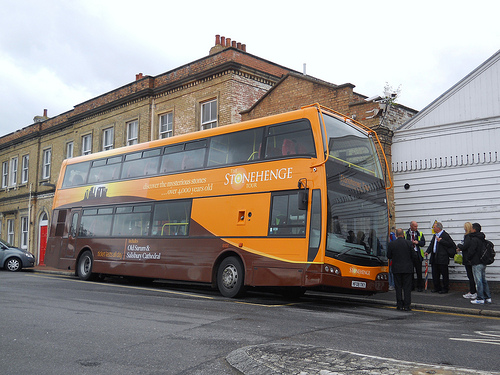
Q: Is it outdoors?
A: Yes, it is outdoors.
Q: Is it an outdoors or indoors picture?
A: It is outdoors.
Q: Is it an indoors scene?
A: No, it is outdoors.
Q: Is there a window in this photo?
A: Yes, there are windows.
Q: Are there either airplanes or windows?
A: Yes, there are windows.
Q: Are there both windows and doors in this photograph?
A: Yes, there are both windows and a door.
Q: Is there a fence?
A: No, there are no fences.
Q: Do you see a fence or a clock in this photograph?
A: No, there are no fences or clocks.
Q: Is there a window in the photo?
A: Yes, there are windows.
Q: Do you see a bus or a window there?
A: Yes, there are windows.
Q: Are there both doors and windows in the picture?
A: Yes, there are both windows and a door.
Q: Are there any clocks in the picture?
A: No, there are no clocks.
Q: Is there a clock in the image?
A: No, there are no clocks.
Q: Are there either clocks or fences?
A: No, there are no clocks or fences.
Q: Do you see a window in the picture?
A: Yes, there are windows.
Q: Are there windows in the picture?
A: Yes, there are windows.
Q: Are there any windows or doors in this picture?
A: Yes, there are windows.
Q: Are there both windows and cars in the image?
A: Yes, there are both windows and a car.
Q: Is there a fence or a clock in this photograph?
A: No, there are no fences or clocks.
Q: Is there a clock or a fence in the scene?
A: No, there are no fences or clocks.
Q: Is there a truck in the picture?
A: No, there are no trucks.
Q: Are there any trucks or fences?
A: No, there are no trucks or fences.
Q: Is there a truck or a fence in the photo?
A: No, there are no trucks or fences.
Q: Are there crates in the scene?
A: No, there are no crates.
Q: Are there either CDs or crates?
A: No, there are no crates or cds.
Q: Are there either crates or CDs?
A: No, there are no crates or cds.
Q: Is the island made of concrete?
A: Yes, the island is made of concrete.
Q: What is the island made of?
A: The island is made of concrete.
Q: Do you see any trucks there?
A: No, there are no trucks.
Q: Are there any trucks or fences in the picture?
A: No, there are no trucks or fences.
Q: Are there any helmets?
A: No, there are no helmets.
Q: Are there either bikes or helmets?
A: No, there are no helmets or bikes.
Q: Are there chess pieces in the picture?
A: No, there are no chess pieces.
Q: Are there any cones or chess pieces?
A: No, there are no chess pieces or cones.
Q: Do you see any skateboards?
A: No, there are no skateboards.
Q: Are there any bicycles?
A: No, there are no bicycles.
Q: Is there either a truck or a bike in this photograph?
A: No, there are no bikes or trucks.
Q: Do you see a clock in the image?
A: No, there are no clocks.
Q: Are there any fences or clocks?
A: No, there are no clocks or fences.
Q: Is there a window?
A: Yes, there is a window.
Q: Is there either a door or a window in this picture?
A: Yes, there is a window.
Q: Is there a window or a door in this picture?
A: Yes, there is a window.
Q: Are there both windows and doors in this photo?
A: Yes, there are both a window and a door.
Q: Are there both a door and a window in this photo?
A: Yes, there are both a window and a door.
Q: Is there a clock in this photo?
A: No, there are no clocks.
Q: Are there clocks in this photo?
A: No, there are no clocks.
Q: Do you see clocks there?
A: No, there are no clocks.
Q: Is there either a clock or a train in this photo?
A: No, there are no clocks or trains.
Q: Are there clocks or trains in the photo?
A: No, there are no clocks or trains.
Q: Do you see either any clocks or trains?
A: No, there are no clocks or trains.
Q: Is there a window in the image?
A: Yes, there are windows.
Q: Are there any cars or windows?
A: Yes, there are windows.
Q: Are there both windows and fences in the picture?
A: No, there are windows but no fences.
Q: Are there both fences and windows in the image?
A: No, there are windows but no fences.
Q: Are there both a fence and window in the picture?
A: No, there are windows but no fences.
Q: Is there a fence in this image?
A: No, there are no fences.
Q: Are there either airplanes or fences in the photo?
A: No, there are no fences or airplanes.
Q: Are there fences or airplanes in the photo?
A: No, there are no fences or airplanes.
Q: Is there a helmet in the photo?
A: No, there are no helmets.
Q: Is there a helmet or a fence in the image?
A: No, there are no helmets or fences.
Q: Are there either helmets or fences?
A: No, there are no helmets or fences.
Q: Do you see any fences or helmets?
A: No, there are no helmets or fences.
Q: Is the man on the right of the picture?
A: Yes, the man is on the right of the image.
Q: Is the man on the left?
A: No, the man is on the right of the image.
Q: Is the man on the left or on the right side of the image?
A: The man is on the right of the image.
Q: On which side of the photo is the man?
A: The man is on the right of the image.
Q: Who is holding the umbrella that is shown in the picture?
A: The man is holding the umbrella.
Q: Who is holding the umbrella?
A: The man is holding the umbrella.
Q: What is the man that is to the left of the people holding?
A: The man is holding the umbrella.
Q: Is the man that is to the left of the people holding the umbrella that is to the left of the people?
A: Yes, the man is holding the umbrella.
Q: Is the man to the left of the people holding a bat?
A: No, the man is holding the umbrella.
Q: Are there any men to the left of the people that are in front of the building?
A: Yes, there is a man to the left of the people.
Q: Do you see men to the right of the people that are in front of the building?
A: No, the man is to the left of the people.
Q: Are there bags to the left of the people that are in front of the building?
A: No, there is a man to the left of the people.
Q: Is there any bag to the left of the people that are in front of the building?
A: No, there is a man to the left of the people.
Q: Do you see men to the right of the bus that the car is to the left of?
A: Yes, there is a man to the right of the bus.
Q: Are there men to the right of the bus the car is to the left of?
A: Yes, there is a man to the right of the bus.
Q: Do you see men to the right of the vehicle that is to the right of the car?
A: Yes, there is a man to the right of the bus.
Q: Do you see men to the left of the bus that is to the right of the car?
A: No, the man is to the right of the bus.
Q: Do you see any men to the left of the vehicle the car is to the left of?
A: No, the man is to the right of the bus.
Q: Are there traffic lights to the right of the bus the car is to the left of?
A: No, there is a man to the right of the bus.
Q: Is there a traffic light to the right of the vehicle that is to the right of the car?
A: No, there is a man to the right of the bus.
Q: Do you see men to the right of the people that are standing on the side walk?
A: Yes, there is a man to the right of the people.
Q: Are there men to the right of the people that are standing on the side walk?
A: Yes, there is a man to the right of the people.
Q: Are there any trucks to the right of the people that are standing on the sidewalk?
A: No, there is a man to the right of the people.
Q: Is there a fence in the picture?
A: No, there are no fences.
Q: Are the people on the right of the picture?
A: Yes, the people are on the right of the image.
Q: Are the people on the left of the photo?
A: No, the people are on the right of the image.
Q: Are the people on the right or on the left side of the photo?
A: The people are on the right of the image.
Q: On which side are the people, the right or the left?
A: The people are on the right of the image.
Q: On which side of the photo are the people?
A: The people are on the right of the image.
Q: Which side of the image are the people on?
A: The people are on the right of the image.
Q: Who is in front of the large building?
A: The people are in front of the building.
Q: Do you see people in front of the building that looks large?
A: Yes, there are people in front of the building.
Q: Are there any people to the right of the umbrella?
A: Yes, there are people to the right of the umbrella.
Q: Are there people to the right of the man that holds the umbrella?
A: Yes, there are people to the right of the man.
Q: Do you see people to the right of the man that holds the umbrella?
A: Yes, there are people to the right of the man.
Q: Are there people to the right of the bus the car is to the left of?
A: Yes, there are people to the right of the bus.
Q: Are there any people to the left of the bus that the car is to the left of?
A: No, the people are to the right of the bus.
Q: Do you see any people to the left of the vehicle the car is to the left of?
A: No, the people are to the right of the bus.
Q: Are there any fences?
A: No, there are no fences.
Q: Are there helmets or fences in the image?
A: No, there are no fences or helmets.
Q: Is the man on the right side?
A: Yes, the man is on the right of the image.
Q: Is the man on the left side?
A: No, the man is on the right of the image.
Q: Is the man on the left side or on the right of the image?
A: The man is on the right of the image.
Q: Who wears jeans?
A: The man wears jeans.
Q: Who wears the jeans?
A: The man wears jeans.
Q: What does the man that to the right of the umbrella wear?
A: The man wears jeans.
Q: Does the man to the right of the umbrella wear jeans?
A: Yes, the man wears jeans.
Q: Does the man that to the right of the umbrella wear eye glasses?
A: No, the man wears jeans.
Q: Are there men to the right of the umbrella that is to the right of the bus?
A: Yes, there is a man to the right of the umbrella.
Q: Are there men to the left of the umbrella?
A: No, the man is to the right of the umbrella.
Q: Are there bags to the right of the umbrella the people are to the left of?
A: No, there is a man to the right of the umbrella.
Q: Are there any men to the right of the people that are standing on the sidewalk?
A: Yes, there is a man to the right of the people.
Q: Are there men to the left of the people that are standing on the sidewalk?
A: No, the man is to the right of the people.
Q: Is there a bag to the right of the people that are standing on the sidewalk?
A: No, there is a man to the right of the people.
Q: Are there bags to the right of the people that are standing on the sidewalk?
A: No, there is a man to the right of the people.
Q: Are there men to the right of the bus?
A: Yes, there is a man to the right of the bus.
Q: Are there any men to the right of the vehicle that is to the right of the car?
A: Yes, there is a man to the right of the bus.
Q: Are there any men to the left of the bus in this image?
A: No, the man is to the right of the bus.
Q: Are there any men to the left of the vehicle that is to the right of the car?
A: No, the man is to the right of the bus.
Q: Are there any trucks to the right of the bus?
A: No, there is a man to the right of the bus.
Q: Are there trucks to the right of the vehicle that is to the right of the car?
A: No, there is a man to the right of the bus.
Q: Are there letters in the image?
A: Yes, there are letters.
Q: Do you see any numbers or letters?
A: Yes, there are letters.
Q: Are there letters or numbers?
A: Yes, there are letters.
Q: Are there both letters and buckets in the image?
A: No, there are letters but no buckets.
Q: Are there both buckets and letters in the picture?
A: No, there are letters but no buckets.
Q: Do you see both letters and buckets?
A: No, there are letters but no buckets.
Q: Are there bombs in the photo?
A: No, there are no bombs.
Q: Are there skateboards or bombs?
A: No, there are no bombs or skateboards.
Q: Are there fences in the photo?
A: No, there are no fences.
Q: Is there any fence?
A: No, there are no fences.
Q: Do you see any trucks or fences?
A: No, there are no fences or trucks.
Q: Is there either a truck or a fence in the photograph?
A: No, there are no fences or trucks.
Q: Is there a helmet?
A: No, there are no helmets.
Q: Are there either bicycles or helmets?
A: No, there are no helmets or bicycles.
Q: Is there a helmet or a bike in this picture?
A: No, there are no helmets or bikes.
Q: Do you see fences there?
A: No, there are no fences.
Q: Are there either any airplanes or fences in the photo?
A: No, there are no fences or airplanes.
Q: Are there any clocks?
A: No, there are no clocks.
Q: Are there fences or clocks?
A: No, there are no clocks or fences.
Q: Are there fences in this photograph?
A: No, there are no fences.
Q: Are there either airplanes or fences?
A: No, there are no fences or airplanes.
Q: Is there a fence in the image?
A: No, there are no fences.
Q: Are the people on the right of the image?
A: Yes, the people are on the right of the image.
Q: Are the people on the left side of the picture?
A: No, the people are on the right of the image.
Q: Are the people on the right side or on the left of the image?
A: The people are on the right of the image.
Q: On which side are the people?
A: The people are on the right of the image.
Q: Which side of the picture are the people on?
A: The people are on the right of the image.